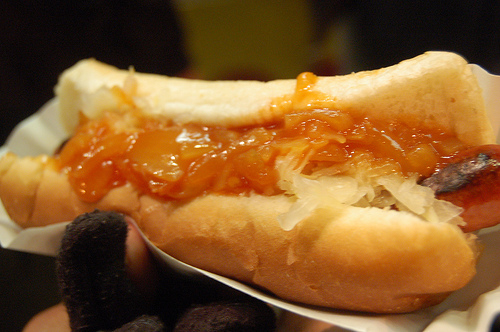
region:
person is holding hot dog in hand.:
[150, 65, 421, 276]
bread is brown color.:
[221, 215, 263, 252]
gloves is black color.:
[70, 227, 100, 292]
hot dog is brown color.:
[465, 185, 485, 220]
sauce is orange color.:
[95, 141, 212, 172]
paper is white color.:
[371, 306, 466, 326]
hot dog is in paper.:
[32, 75, 454, 325]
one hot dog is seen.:
[30, 77, 487, 328]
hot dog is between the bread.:
[38, 71, 487, 260]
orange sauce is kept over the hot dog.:
[49, 124, 394, 184]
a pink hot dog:
[421, 141, 498, 233]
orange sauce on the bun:
[290, 69, 320, 91]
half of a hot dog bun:
[54, 52, 499, 162]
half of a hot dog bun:
[0, 150, 482, 315]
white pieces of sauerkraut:
[272, 162, 374, 232]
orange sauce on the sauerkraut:
[48, 108, 468, 212]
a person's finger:
[21, 210, 151, 330]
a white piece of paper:
[0, 87, 498, 329]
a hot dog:
[0, 53, 499, 318]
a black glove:
[53, 208, 279, 330]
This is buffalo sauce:
[75, 122, 198, 185]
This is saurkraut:
[273, 157, 475, 244]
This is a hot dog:
[409, 152, 499, 228]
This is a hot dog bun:
[6, 62, 483, 289]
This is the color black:
[54, 210, 161, 313]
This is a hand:
[116, 220, 173, 301]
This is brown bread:
[303, 234, 378, 293]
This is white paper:
[167, 245, 287, 307]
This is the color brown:
[127, 33, 162, 46]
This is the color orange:
[400, 122, 421, 139]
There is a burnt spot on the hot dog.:
[413, 153, 491, 193]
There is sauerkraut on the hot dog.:
[286, 170, 415, 210]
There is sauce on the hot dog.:
[96, 119, 262, 208]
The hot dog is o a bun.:
[221, 212, 455, 290]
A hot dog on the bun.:
[47, 122, 498, 193]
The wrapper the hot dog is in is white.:
[293, 302, 487, 330]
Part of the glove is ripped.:
[59, 213, 157, 314]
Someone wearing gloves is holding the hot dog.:
[18, 233, 285, 329]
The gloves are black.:
[174, 294, 281, 329]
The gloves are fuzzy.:
[73, 257, 226, 323]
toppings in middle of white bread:
[20, 32, 493, 302]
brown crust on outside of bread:
[216, 220, 451, 300]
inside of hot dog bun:
[350, 50, 480, 140]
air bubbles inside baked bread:
[390, 60, 480, 126]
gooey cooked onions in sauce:
[52, 91, 267, 201]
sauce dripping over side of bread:
[245, 65, 356, 105]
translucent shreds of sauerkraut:
[266, 165, 461, 236]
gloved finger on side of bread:
[45, 195, 135, 300]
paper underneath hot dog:
[125, 230, 342, 327]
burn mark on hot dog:
[400, 140, 496, 201]